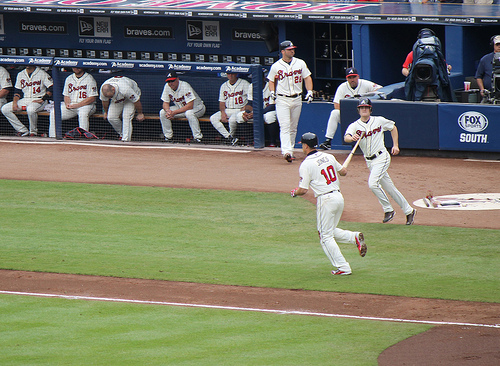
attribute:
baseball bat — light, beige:
[338, 144, 363, 169]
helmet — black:
[296, 129, 320, 148]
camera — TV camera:
[399, 30, 454, 104]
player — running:
[337, 95, 418, 226]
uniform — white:
[341, 110, 413, 215]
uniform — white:
[296, 148, 356, 268]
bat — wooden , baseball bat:
[339, 122, 367, 184]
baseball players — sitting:
[1, 63, 260, 138]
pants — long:
[313, 183, 399, 283]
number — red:
[316, 160, 343, 191]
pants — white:
[304, 198, 361, 261]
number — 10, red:
[314, 164, 341, 185]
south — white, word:
[459, 129, 491, 146]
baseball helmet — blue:
[292, 130, 322, 152]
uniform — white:
[345, 115, 414, 211]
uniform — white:
[298, 152, 355, 272]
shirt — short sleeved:
[297, 148, 345, 197]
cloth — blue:
[403, 30, 451, 101]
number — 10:
[319, 163, 337, 186]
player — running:
[291, 130, 367, 275]